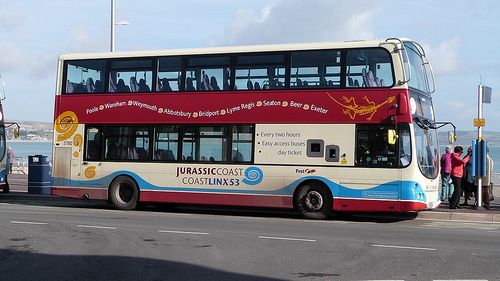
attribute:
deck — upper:
[64, 62, 396, 82]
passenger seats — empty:
[75, 69, 382, 86]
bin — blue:
[22, 156, 47, 194]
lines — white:
[9, 216, 453, 258]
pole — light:
[108, 0, 118, 55]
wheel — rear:
[107, 175, 139, 211]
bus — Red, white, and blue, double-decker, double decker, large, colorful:
[52, 37, 444, 222]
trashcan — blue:
[23, 155, 49, 197]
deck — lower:
[53, 123, 429, 211]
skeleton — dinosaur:
[321, 98, 391, 122]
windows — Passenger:
[79, 118, 254, 164]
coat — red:
[448, 152, 466, 184]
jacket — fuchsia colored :
[439, 152, 454, 174]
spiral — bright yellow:
[46, 99, 103, 146]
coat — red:
[449, 149, 470, 178]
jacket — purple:
[440, 151, 453, 173]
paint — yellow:
[53, 110, 78, 146]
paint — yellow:
[70, 133, 83, 149]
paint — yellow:
[71, 150, 80, 158]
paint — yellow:
[82, 164, 97, 179]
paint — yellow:
[323, 88, 396, 123]